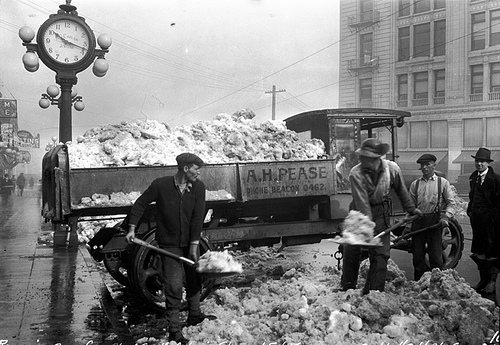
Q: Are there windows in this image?
A: Yes, there is a window.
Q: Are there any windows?
A: Yes, there is a window.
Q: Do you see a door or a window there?
A: Yes, there is a window.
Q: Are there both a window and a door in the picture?
A: No, there is a window but no doors.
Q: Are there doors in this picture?
A: No, there are no doors.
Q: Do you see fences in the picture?
A: No, there are no fences.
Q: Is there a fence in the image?
A: No, there are no fences.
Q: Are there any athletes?
A: No, there are no athletes.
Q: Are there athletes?
A: No, there are no athletes.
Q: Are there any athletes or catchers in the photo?
A: No, there are no athletes or catchers.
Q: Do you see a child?
A: No, there are no children.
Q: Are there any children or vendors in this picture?
A: No, there are no children or vendors.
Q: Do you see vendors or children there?
A: No, there are no children or vendors.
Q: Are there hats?
A: Yes, there is a hat.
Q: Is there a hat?
A: Yes, there is a hat.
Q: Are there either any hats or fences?
A: Yes, there is a hat.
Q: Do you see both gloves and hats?
A: No, there is a hat but no gloves.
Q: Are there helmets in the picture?
A: No, there are no helmets.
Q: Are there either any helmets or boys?
A: No, there are no helmets or boys.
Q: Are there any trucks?
A: Yes, there is a truck.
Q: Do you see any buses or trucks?
A: Yes, there is a truck.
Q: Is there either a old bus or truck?
A: Yes, there is an old truck.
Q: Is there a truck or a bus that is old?
A: Yes, the truck is old.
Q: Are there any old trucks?
A: Yes, there is an old truck.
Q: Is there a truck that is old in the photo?
A: Yes, there is an old truck.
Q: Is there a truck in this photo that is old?
A: Yes, there is a truck that is old.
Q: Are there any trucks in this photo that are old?
A: Yes, there is a truck that is old.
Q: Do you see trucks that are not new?
A: Yes, there is a old truck.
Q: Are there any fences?
A: No, there are no fences.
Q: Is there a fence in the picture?
A: No, there are no fences.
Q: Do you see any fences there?
A: No, there are no fences.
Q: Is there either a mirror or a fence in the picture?
A: No, there are no fences or mirrors.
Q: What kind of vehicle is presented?
A: The vehicle is a truck.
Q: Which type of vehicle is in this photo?
A: The vehicle is a truck.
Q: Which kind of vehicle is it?
A: The vehicle is a truck.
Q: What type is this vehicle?
A: This is a truck.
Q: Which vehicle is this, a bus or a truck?
A: This is a truck.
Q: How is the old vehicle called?
A: The vehicle is a truck.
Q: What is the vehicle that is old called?
A: The vehicle is a truck.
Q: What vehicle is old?
A: The vehicle is a truck.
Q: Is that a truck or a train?
A: That is a truck.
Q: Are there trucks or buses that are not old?
A: No, there is a truck but it is old.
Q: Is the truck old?
A: Yes, the truck is old.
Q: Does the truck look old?
A: Yes, the truck is old.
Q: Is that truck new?
A: No, the truck is old.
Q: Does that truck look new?
A: No, the truck is old.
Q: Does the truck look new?
A: No, the truck is old.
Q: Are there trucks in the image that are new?
A: No, there is a truck but it is old.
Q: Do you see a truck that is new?
A: No, there is a truck but it is old.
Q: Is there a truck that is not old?
A: No, there is a truck but it is old.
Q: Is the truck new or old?
A: The truck is old.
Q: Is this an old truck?
A: Yes, this is an old truck.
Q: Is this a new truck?
A: No, this is an old truck.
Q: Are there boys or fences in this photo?
A: No, there are no fences or boys.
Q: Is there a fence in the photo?
A: No, there are no fences.